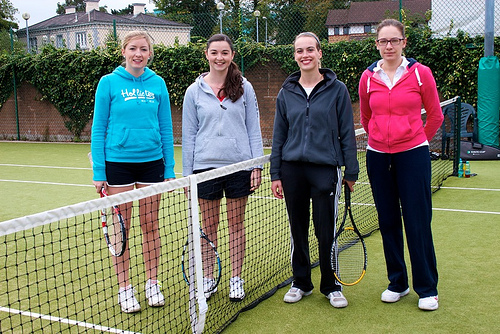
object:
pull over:
[90, 62, 177, 183]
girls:
[266, 31, 358, 307]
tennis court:
[0, 135, 500, 334]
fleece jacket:
[358, 57, 442, 154]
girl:
[358, 18, 443, 312]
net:
[0, 96, 464, 334]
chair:
[441, 102, 478, 154]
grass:
[436, 244, 500, 332]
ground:
[431, 181, 500, 237]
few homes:
[12, 0, 193, 59]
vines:
[277, 43, 373, 100]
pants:
[279, 161, 342, 294]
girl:
[89, 30, 176, 314]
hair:
[121, 30, 156, 63]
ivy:
[36, 33, 126, 141]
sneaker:
[381, 285, 411, 302]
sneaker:
[418, 290, 440, 311]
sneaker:
[284, 282, 312, 303]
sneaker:
[325, 292, 349, 308]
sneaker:
[227, 277, 245, 301]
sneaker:
[117, 283, 140, 313]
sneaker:
[146, 278, 165, 307]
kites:
[192, 167, 252, 199]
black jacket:
[269, 67, 360, 182]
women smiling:
[87, 30, 359, 314]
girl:
[181, 33, 265, 302]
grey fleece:
[181, 71, 262, 178]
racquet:
[97, 186, 128, 257]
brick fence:
[0, 56, 476, 143]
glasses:
[374, 37, 405, 46]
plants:
[425, 18, 498, 103]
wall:
[4, 88, 468, 143]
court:
[0, 140, 500, 334]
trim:
[106, 180, 165, 182]